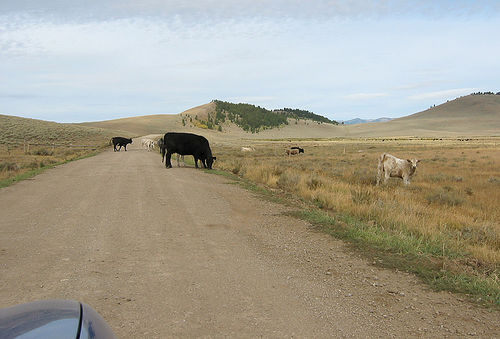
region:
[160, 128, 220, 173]
black cow grazing on the road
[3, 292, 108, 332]
part of a blue vehicle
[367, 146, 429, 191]
white cow in the field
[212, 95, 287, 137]
trees on the hill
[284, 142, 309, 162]
cows in the field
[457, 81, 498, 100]
trees on the hilltop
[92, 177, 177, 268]
worn beaten tan path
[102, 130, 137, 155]
cow crossing the road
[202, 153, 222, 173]
head of the cow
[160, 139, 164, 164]
tail on the cow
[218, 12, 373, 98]
this is the sky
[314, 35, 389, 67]
the sky is blue in color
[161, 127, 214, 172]
this is a cow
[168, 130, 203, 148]
the cow is black in color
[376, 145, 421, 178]
this is a goat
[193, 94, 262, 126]
this is a hill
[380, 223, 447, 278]
this is a grass area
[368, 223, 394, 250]
the grass is green in color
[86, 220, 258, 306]
this is the road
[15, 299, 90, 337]
this is a vehicle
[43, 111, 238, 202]
several cows standing on a road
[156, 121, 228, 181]
a black cow eating grass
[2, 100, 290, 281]
a dirt road way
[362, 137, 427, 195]
a white and brown cow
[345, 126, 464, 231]
a cow standing in a field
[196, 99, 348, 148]
a hillside covered with trees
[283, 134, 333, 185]
two cows in a field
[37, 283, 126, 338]
the front of a vehicle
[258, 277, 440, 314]
gravel on a road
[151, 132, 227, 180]
a black cow grazing on grass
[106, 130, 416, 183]
Several cows in the countryside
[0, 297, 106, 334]
Side of a car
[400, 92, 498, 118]
A small distant hill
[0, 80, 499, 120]
A clear sunny sky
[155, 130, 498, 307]
A large wide open field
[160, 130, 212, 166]
A large black cow grazing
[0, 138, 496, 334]
A long stretch of dirt road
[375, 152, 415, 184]
A large white cow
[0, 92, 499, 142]
Several large grassy hills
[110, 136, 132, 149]
A black cow in the middle of a dirt road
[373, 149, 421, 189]
a white cow standing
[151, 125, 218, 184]
a black bull on road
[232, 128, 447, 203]
cowa grazing in field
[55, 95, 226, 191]
several cows corring the road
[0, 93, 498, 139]
rolling hills in background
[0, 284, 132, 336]
the hood of a car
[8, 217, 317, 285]
a gravel road between field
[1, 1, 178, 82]
white clouds in the sky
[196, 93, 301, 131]
a patch of green trees on the hill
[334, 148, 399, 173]
the tail of a white cow